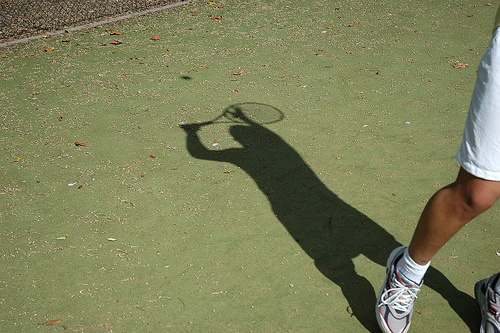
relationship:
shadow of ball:
[180, 72, 192, 79] [179, 64, 192, 86]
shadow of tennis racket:
[174, 90, 486, 332] [180, 100, 283, 132]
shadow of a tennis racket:
[174, 90, 486, 332] [184, 92, 285, 143]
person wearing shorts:
[376, 7, 498, 329] [454, 24, 498, 185]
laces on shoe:
[383, 264, 422, 319] [375, 245, 424, 331]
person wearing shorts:
[376, 7, 498, 329] [466, 37, 496, 182]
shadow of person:
[174, 90, 486, 332] [376, 7, 498, 329]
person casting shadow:
[376, 7, 498, 329] [174, 90, 486, 332]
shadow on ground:
[174, 90, 486, 332] [0, 0, 499, 330]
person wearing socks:
[376, 7, 498, 329] [396, 240, 498, 295]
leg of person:
[374, 78, 498, 330] [376, 7, 498, 329]